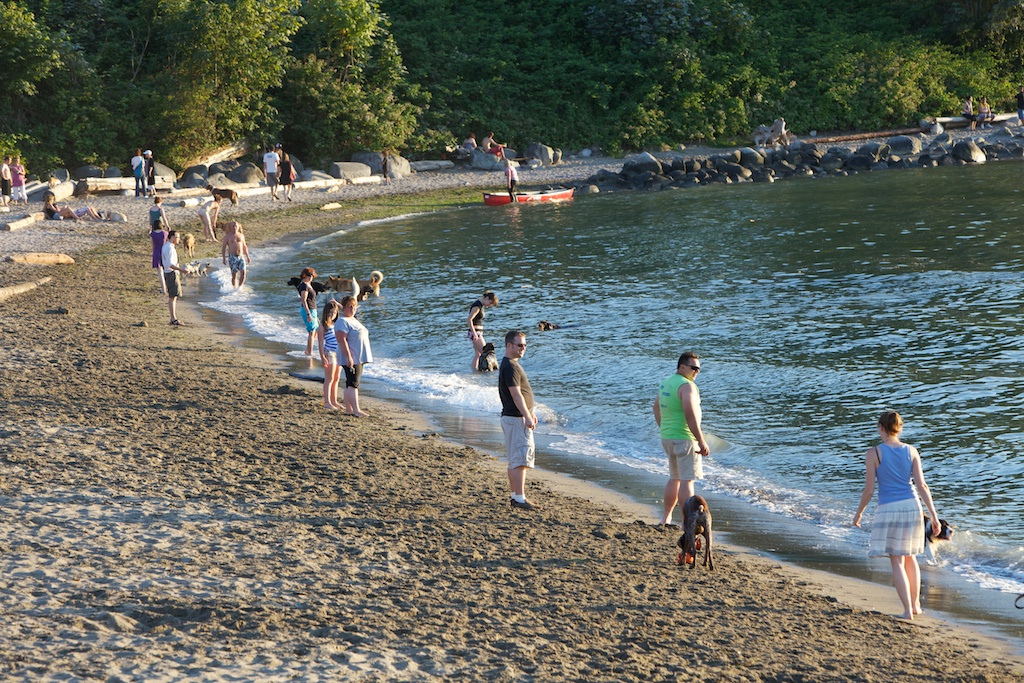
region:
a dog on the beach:
[674, 493, 712, 566]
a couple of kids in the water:
[466, 290, 498, 377]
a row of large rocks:
[582, 126, 1016, 191]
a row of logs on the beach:
[226, 173, 376, 205]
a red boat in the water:
[484, 179, 570, 206]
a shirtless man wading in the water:
[216, 217, 254, 295]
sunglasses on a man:
[680, 360, 703, 374]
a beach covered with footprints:
[1, 263, 1008, 675]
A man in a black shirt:
[488, 330, 545, 512]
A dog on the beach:
[673, 494, 716, 580]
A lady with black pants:
[335, 293, 374, 412]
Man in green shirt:
[655, 344, 713, 509]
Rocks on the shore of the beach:
[617, 151, 897, 187]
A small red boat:
[488, 178, 590, 218]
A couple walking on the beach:
[247, 135, 309, 202]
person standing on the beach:
[848, 403, 946, 622]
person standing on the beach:
[649, 349, 714, 527]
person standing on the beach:
[495, 321, 544, 511]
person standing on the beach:
[462, 283, 500, 366]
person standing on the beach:
[329, 283, 374, 408]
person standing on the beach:
[317, 292, 346, 409]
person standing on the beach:
[292, 261, 318, 372]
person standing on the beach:
[162, 226, 183, 318]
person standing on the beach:
[144, 191, 163, 265]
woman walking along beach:
[839, 404, 947, 626]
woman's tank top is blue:
[854, 435, 931, 518]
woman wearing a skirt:
[851, 492, 929, 563]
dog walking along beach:
[665, 491, 719, 577]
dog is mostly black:
[676, 488, 719, 577]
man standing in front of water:
[643, 340, 723, 537]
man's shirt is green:
[648, 366, 712, 452]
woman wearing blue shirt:
[854, 406, 937, 622]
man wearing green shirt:
[648, 342, 710, 529]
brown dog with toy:
[668, 488, 716, 575]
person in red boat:
[484, 149, 576, 207]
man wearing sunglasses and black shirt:
[491, 330, 546, 511]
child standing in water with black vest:
[462, 291, 502, 378]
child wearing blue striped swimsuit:
[320, 296, 341, 408]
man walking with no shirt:
[219, 216, 254, 294]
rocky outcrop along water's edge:
[563, 127, 1022, 192]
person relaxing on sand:
[40, 185, 118, 224]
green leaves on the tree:
[291, 2, 337, 67]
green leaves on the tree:
[659, 15, 729, 132]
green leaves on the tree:
[764, 24, 831, 101]